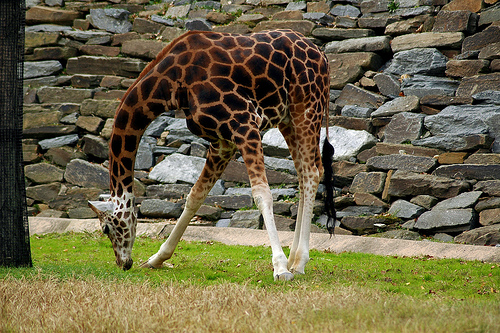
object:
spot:
[198, 102, 232, 124]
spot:
[188, 81, 220, 106]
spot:
[221, 92, 247, 112]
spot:
[238, 54, 276, 89]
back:
[154, 27, 330, 119]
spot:
[182, 34, 214, 54]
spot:
[233, 33, 255, 52]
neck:
[105, 56, 166, 172]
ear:
[89, 196, 105, 224]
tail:
[321, 94, 338, 238]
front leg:
[239, 144, 292, 282]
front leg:
[143, 138, 232, 268]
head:
[88, 189, 136, 270]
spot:
[267, 62, 284, 86]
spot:
[234, 35, 256, 45]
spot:
[292, 55, 307, 73]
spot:
[192, 81, 220, 103]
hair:
[321, 137, 334, 238]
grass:
[0, 281, 100, 332]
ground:
[0, 215, 500, 331]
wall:
[339, 13, 491, 200]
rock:
[354, 47, 411, 117]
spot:
[209, 59, 232, 79]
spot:
[243, 52, 269, 75]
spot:
[270, 34, 294, 57]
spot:
[159, 67, 184, 81]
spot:
[251, 41, 273, 58]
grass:
[271, 283, 438, 312]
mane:
[98, 144, 125, 216]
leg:
[292, 109, 320, 278]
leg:
[280, 118, 302, 269]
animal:
[87, 27, 337, 283]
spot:
[264, 57, 287, 87]